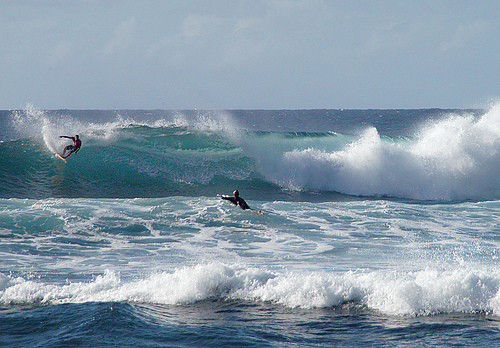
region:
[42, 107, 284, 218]
two people are in the ocean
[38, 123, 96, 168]
this person is riding the wave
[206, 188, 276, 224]
this person is in the water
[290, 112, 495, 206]
the wave is splashing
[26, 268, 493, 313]
the splashing makes the water appear white in color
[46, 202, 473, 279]
the water here appears soapy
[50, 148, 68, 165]
the person is on the surfboard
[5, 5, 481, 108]
the sky is blue in color with some white clouds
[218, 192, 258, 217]
the person is in a wet suite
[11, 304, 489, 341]
small waves are in this part of the water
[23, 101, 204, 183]
a surfer riding a wave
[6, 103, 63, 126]
seawater splashing water drops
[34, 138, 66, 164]
surfboard cutting through the water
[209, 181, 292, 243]
surfer paddling out to waves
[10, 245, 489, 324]
waves breaking on surface of water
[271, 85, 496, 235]
large wave breaking on the ocean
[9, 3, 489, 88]
a semi-cloudy ski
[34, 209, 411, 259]
foam on top of the ocean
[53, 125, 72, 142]
the arm of a surfer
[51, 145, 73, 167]
the legs of a surfer on the surfboard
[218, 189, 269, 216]
a man in the water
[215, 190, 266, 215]
the person is paddling on a board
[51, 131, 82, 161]
a man on a surfboard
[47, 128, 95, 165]
a surfer riding the wave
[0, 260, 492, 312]
a small wave in the ocean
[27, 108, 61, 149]
water spray from the surfboard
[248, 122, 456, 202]
wave crashing into the water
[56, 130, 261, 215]
two people in the water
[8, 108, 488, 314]
large waves in the ocean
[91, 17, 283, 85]
light clouds in the sky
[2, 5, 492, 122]
clear blue sky over dark-grey ocean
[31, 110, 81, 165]
curve of water under surfer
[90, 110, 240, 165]
greenish water between split wave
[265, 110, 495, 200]
crashing white wave creating droplets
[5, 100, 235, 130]
white water jumping out of ocean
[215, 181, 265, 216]
surfer lying on board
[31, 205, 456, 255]
lacy seafoam on water surface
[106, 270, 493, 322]
curved edge of low wave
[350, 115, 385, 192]
vertical curve on wave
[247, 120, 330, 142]
curve of dark water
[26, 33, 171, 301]
The person is out in the ocean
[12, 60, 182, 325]
The person is close to the beach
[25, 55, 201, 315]
The person is doing some surfing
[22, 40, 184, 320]
The person is on an ocean wave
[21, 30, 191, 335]
The person is on their vacation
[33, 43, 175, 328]
A person is having a great time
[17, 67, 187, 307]
A person is out in the daytime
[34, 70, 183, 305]
A person is enjoying the day